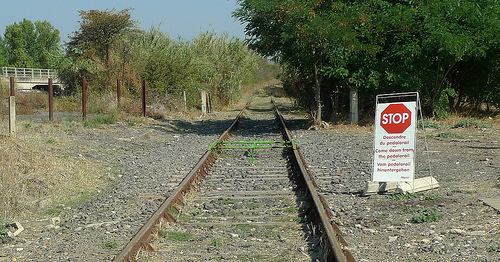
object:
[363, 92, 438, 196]
holder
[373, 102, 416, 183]
sign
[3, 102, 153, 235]
grass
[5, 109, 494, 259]
gravel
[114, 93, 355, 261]
track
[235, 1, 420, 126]
tree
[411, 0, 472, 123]
tree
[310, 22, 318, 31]
leaf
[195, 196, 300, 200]
tie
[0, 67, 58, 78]
rail